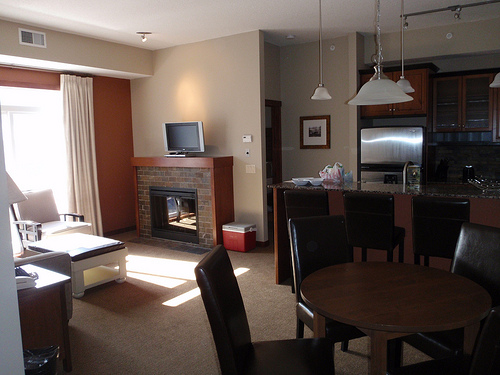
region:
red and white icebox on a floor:
[218, 220, 261, 255]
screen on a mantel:
[158, 119, 205, 159]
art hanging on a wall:
[295, 112, 332, 152]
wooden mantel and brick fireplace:
[124, 154, 234, 252]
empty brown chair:
[193, 242, 342, 372]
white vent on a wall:
[17, 27, 49, 50]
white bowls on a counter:
[289, 174, 326, 186]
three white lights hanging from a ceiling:
[308, 0, 418, 109]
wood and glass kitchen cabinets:
[428, 71, 497, 134]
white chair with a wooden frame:
[7, 187, 96, 241]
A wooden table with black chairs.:
[190, 215, 498, 370]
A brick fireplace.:
[133, 165, 213, 246]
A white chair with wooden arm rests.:
[7, 185, 92, 246]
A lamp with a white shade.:
[0, 165, 40, 257]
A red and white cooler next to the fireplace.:
[220, 217, 255, 249]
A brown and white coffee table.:
[20, 230, 125, 296]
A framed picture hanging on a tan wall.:
[295, 111, 332, 147]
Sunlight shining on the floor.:
[111, 230, 250, 310]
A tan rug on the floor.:
[21, 240, 451, 365]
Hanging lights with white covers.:
[308, 5, 497, 106]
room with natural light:
[7, 6, 494, 368]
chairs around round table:
[199, 213, 493, 371]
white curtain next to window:
[0, 73, 107, 231]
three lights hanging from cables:
[311, 0, 415, 107]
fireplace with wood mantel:
[133, 155, 232, 243]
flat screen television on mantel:
[129, 119, 231, 168]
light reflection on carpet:
[116, 254, 249, 306]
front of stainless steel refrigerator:
[357, 123, 423, 182]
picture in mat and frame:
[298, 114, 333, 149]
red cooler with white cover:
[220, 220, 257, 252]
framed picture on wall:
[293, 110, 338, 154]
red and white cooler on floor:
[218, 218, 262, 255]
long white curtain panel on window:
[53, 73, 107, 248]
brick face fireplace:
[130, 153, 230, 250]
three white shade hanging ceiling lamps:
[311, 40, 419, 112]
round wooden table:
[293, 261, 498, 372]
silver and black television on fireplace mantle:
[156, 116, 215, 159]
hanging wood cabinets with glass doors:
[431, 65, 496, 139]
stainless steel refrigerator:
[351, 120, 429, 192]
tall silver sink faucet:
[397, 155, 416, 188]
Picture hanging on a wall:
[299, 115, 330, 147]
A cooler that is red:
[222, 220, 256, 251]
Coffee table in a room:
[22, 232, 125, 295]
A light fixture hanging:
[345, 0, 412, 103]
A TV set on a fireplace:
[163, 121, 204, 156]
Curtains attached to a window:
[60, 75, 101, 233]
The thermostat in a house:
[241, 134, 251, 143]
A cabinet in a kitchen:
[432, 78, 462, 131]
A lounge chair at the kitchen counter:
[343, 190, 403, 262]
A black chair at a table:
[194, 243, 334, 374]